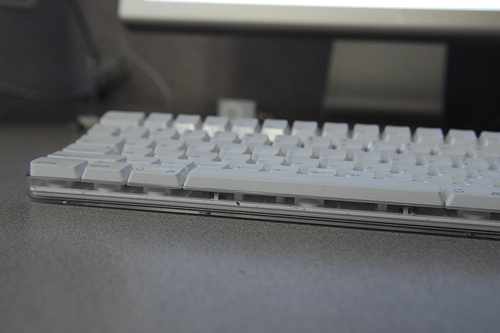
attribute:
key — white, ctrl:
[30, 156, 88, 178]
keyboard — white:
[106, 120, 481, 232]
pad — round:
[43, 181, 65, 188]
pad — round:
[97, 183, 114, 193]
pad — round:
[145, 186, 164, 197]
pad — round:
[296, 197, 318, 208]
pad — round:
[458, 212, 488, 219]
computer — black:
[33, 0, 495, 276]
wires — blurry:
[87, 32, 179, 104]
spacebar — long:
[182, 166, 444, 207]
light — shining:
[173, 103, 287, 142]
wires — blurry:
[134, 52, 168, 92]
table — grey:
[13, 129, 475, 331]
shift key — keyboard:
[49, 152, 122, 164]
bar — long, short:
[183, 166, 444, 208]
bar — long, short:
[444, 184, 498, 212]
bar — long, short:
[127, 163, 189, 188]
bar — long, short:
[81, 159, 131, 184]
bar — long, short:
[27, 155, 84, 181]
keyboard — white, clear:
[26, 109, 499, 239]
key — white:
[203, 115, 226, 132]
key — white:
[262, 118, 287, 136]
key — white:
[324, 121, 349, 137]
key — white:
[384, 125, 411, 141]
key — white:
[447, 127, 477, 144]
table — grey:
[51, 226, 316, 312]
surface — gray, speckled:
[6, 118, 495, 330]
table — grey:
[6, 108, 498, 328]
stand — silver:
[321, 36, 456, 125]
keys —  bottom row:
[122, 159, 300, 184]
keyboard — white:
[33, 105, 480, 217]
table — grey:
[5, 236, 495, 327]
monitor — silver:
[114, 6, 498, 117]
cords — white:
[106, 38, 180, 102]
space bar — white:
[181, 164, 443, 207]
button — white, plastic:
[122, 159, 194, 186]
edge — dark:
[126, 18, 498, 54]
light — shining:
[170, 110, 293, 141]